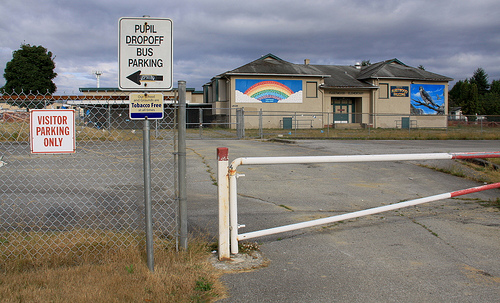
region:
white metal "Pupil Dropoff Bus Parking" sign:
[111, 12, 178, 96]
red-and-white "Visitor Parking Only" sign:
[25, 107, 82, 157]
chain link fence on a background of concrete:
[17, 162, 124, 227]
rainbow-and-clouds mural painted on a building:
[233, 75, 306, 107]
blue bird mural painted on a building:
[409, 81, 447, 118]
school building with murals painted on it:
[201, 32, 458, 143]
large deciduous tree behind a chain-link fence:
[1, 34, 66, 100]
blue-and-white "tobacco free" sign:
[124, 89, 170, 124]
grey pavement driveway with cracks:
[373, 221, 491, 301]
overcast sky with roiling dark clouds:
[183, 2, 495, 55]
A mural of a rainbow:
[233, 75, 303, 105]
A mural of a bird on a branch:
[410, 82, 448, 115]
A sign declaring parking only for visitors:
[27, 110, 77, 153]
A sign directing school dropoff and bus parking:
[121, 17, 173, 89]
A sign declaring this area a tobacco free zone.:
[128, 90, 164, 120]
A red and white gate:
[214, 138, 496, 263]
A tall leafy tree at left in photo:
[0, 42, 65, 118]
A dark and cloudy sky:
[1, 0, 497, 72]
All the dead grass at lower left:
[0, 234, 218, 301]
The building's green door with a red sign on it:
[333, 97, 358, 127]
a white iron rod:
[213, 151, 255, 264]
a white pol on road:
[234, 150, 489, 242]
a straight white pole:
[199, 150, 239, 290]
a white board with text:
[98, 13, 187, 138]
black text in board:
[123, 3, 186, 111]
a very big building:
[217, 65, 479, 150]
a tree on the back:
[6, 45, 71, 130]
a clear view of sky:
[21, 10, 494, 89]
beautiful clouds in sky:
[63, 18, 423, 60]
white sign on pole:
[121, 20, 171, 90]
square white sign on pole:
[117, 15, 174, 99]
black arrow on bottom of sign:
[122, 68, 170, 86]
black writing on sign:
[122, 20, 166, 70]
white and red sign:
[26, 108, 79, 153]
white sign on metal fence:
[18, 100, 82, 160]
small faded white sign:
[127, 91, 160, 117]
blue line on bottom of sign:
[131, 108, 163, 120]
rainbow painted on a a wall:
[246, 78, 291, 105]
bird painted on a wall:
[409, 83, 443, 115]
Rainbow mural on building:
[233, 76, 305, 104]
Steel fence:
[0, 78, 192, 261]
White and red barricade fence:
[210, 144, 497, 265]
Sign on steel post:
[118, 14, 174, 275]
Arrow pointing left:
[126, 67, 163, 89]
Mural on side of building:
[405, 80, 447, 118]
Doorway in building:
[332, 100, 357, 129]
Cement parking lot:
[3, 139, 498, 297]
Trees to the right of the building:
[450, 67, 497, 129]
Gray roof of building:
[210, 54, 450, 87]